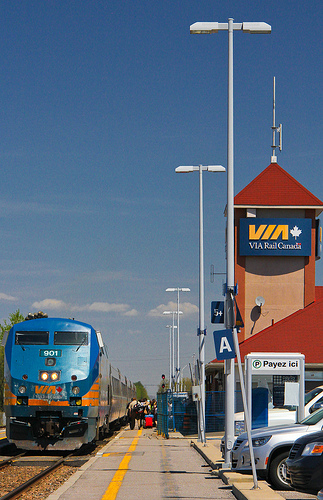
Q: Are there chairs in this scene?
A: No, there are no chairs.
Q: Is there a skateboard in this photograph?
A: No, there are no skateboards.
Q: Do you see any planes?
A: No, there are no planes.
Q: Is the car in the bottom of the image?
A: Yes, the car is in the bottom of the image.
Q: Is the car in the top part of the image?
A: No, the car is in the bottom of the image.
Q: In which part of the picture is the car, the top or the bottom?
A: The car is in the bottom of the image.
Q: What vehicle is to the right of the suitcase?
A: The vehicle is a car.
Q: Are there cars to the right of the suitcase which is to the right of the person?
A: Yes, there is a car to the right of the suitcase.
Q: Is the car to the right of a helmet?
A: No, the car is to the right of the suitcase.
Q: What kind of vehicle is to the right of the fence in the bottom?
A: The vehicle is a car.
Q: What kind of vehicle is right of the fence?
A: The vehicle is a car.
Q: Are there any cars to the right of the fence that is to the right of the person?
A: Yes, there is a car to the right of the fence.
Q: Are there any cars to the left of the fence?
A: No, the car is to the right of the fence.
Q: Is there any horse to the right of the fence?
A: No, there is a car to the right of the fence.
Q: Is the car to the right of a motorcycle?
A: No, the car is to the right of the fence.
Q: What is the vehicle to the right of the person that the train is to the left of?
A: The vehicle is a car.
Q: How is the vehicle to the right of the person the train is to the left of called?
A: The vehicle is a car.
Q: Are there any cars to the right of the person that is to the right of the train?
A: Yes, there is a car to the right of the person.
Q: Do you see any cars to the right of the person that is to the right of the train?
A: Yes, there is a car to the right of the person.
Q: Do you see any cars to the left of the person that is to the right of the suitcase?
A: No, the car is to the right of the person.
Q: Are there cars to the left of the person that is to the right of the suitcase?
A: No, the car is to the right of the person.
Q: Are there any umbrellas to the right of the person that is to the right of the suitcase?
A: No, there is a car to the right of the person.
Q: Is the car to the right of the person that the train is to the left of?
A: Yes, the car is to the right of the person.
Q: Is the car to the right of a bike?
A: No, the car is to the right of the person.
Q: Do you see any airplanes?
A: No, there are no airplanes.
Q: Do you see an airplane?
A: No, there are no airplanes.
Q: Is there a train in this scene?
A: Yes, there is a train.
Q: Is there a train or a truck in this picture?
A: Yes, there is a train.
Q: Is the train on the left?
A: Yes, the train is on the left of the image.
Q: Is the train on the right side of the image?
A: No, the train is on the left of the image.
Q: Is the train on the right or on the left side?
A: The train is on the left of the image.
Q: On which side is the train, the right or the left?
A: The train is on the left of the image.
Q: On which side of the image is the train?
A: The train is on the left of the image.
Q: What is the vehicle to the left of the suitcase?
A: The vehicle is a train.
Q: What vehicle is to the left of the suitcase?
A: The vehicle is a train.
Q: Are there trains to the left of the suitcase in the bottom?
A: Yes, there is a train to the left of the suitcase.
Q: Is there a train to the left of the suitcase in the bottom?
A: Yes, there is a train to the left of the suitcase.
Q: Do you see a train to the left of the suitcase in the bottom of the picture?
A: Yes, there is a train to the left of the suitcase.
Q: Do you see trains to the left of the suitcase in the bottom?
A: Yes, there is a train to the left of the suitcase.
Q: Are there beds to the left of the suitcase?
A: No, there is a train to the left of the suitcase.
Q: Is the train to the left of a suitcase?
A: Yes, the train is to the left of a suitcase.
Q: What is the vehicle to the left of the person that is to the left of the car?
A: The vehicle is a train.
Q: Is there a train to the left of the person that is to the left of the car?
A: Yes, there is a train to the left of the person.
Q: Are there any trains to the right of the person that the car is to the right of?
A: No, the train is to the left of the person.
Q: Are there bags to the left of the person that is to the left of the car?
A: No, there is a train to the left of the person.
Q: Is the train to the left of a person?
A: Yes, the train is to the left of a person.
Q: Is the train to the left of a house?
A: No, the train is to the left of a person.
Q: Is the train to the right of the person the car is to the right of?
A: No, the train is to the left of the person.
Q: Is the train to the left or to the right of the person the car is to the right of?
A: The train is to the left of the person.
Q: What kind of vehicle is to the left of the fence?
A: The vehicle is a train.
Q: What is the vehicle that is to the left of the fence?
A: The vehicle is a train.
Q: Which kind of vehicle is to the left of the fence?
A: The vehicle is a train.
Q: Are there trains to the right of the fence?
A: No, the train is to the left of the fence.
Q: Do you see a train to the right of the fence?
A: No, the train is to the left of the fence.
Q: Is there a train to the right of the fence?
A: No, the train is to the left of the fence.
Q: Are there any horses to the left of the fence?
A: No, there is a train to the left of the fence.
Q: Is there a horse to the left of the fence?
A: No, there is a train to the left of the fence.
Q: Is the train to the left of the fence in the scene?
A: Yes, the train is to the left of the fence.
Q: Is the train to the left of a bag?
A: No, the train is to the left of the fence.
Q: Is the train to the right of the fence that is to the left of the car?
A: No, the train is to the left of the fence.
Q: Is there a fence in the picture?
A: Yes, there is a fence.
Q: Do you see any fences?
A: Yes, there is a fence.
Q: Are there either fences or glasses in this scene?
A: Yes, there is a fence.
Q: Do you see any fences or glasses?
A: Yes, there is a fence.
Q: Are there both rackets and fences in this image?
A: No, there is a fence but no rackets.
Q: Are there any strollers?
A: No, there are no strollers.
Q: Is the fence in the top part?
A: No, the fence is in the bottom of the image.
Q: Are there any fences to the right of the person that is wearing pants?
A: Yes, there is a fence to the right of the person.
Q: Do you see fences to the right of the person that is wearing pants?
A: Yes, there is a fence to the right of the person.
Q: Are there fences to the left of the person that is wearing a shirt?
A: No, the fence is to the right of the person.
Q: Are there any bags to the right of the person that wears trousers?
A: No, there is a fence to the right of the person.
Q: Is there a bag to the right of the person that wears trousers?
A: No, there is a fence to the right of the person.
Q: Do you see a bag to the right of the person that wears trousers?
A: No, there is a fence to the right of the person.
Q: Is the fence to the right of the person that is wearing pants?
A: Yes, the fence is to the right of the person.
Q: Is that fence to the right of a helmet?
A: No, the fence is to the right of the person.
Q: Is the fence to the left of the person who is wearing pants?
A: No, the fence is to the right of the person.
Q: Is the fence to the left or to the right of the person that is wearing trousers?
A: The fence is to the right of the person.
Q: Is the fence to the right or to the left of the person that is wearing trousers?
A: The fence is to the right of the person.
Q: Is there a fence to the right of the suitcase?
A: Yes, there is a fence to the right of the suitcase.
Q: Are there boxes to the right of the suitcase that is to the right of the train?
A: No, there is a fence to the right of the suitcase.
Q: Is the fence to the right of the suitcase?
A: Yes, the fence is to the right of the suitcase.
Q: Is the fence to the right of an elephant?
A: No, the fence is to the right of the suitcase.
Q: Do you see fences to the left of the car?
A: Yes, there is a fence to the left of the car.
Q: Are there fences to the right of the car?
A: No, the fence is to the left of the car.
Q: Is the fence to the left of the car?
A: Yes, the fence is to the left of the car.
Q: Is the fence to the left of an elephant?
A: No, the fence is to the left of the car.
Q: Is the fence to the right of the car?
A: No, the fence is to the left of the car.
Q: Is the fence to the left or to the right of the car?
A: The fence is to the left of the car.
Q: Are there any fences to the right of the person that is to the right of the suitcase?
A: Yes, there is a fence to the right of the person.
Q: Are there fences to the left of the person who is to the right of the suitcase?
A: No, the fence is to the right of the person.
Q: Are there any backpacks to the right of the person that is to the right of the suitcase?
A: No, there is a fence to the right of the person.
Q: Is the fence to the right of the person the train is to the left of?
A: Yes, the fence is to the right of the person.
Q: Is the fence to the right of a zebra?
A: No, the fence is to the right of the person.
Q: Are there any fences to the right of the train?
A: Yes, there is a fence to the right of the train.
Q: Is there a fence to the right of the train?
A: Yes, there is a fence to the right of the train.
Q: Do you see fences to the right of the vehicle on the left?
A: Yes, there is a fence to the right of the train.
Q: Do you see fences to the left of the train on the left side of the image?
A: No, the fence is to the right of the train.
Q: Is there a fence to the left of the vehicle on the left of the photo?
A: No, the fence is to the right of the train.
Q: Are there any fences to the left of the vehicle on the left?
A: No, the fence is to the right of the train.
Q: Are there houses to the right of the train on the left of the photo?
A: No, there is a fence to the right of the train.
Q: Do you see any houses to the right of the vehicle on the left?
A: No, there is a fence to the right of the train.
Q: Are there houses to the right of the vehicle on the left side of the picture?
A: No, there is a fence to the right of the train.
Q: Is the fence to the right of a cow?
A: No, the fence is to the right of the train.